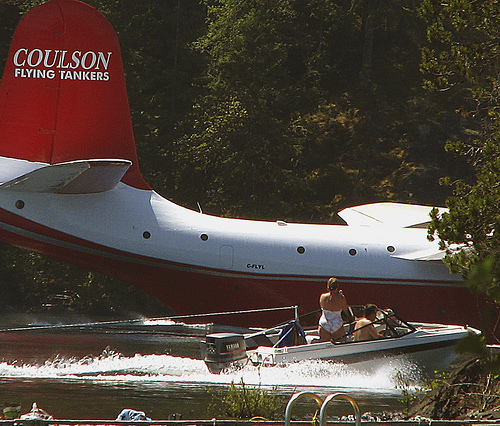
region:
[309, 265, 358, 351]
A woman wearing a white bathin suit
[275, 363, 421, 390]
White water spray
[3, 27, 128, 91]
A logo on an airplane tail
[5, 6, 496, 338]
A white and red airplane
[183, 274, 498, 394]
A motorboat with two people riding in it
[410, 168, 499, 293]
Tree branches with green leaves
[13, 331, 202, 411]
Water in a lake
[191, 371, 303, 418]
A green bush next to a lake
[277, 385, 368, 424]
Two silver metal bars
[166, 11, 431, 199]
Trees growing in the background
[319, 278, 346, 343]
woman in a white swimsuit on a boat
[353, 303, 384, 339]
man driving the boat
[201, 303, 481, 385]
white boat in the river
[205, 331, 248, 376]
engine of a white boat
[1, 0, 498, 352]
white and red airplane in the river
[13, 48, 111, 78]
logo of the airplane company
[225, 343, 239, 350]
logo of the black engine of the boat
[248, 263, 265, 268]
black letters on the side of the airplane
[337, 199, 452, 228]
left wing of the airplane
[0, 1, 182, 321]
tail of the airplane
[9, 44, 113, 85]
white lettering on red background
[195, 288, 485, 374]
boat traveling in the water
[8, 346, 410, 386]
wake boat is creating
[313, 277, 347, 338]
woman wearing white bathing suit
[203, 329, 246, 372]
engine of white boat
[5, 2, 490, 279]
trees along the river's edge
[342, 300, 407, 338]
front windshield of white boat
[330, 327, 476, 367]
dark stripe on the boat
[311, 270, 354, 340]
woman standing in boat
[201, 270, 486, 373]
people riding motor boat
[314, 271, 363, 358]
woman in bathing suit in motor boat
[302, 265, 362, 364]
woman standing up in motor boat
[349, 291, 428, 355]
man driving motor boat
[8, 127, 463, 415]
motor boat approaching red and white plane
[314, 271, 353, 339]
woman in one-piece bathing suit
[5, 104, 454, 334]
large red and white plane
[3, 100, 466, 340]
large red and white aircraft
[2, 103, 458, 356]
huge red and white plane in water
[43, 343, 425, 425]
splash behind motor boat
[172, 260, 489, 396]
Boat on the water.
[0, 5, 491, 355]
Airplane on the water.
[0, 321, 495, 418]
Water in the forefront.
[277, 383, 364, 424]
Handles on the ladder.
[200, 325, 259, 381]
Motor on the boat.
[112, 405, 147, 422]
clothing on the pier.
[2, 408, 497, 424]
Pier on the water.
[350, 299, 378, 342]
Man drivng a boat.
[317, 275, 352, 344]
Woman standing in the boat.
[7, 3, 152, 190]
Red tail on the plane.